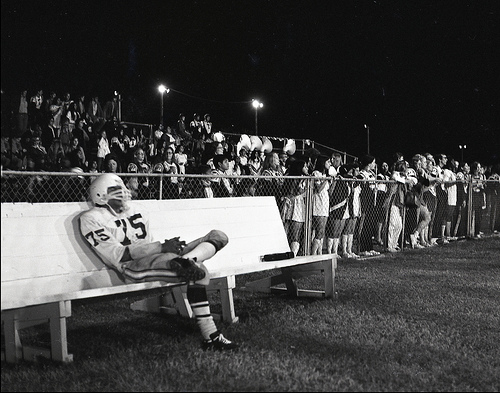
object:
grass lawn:
[0, 234, 500, 367]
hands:
[162, 236, 186, 255]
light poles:
[159, 92, 164, 124]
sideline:
[0, 55, 500, 283]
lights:
[157, 84, 171, 93]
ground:
[0, 228, 500, 366]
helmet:
[88, 172, 133, 205]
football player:
[79, 172, 241, 352]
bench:
[0, 195, 338, 364]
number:
[84, 228, 111, 247]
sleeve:
[76, 206, 126, 269]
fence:
[0, 170, 499, 257]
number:
[115, 212, 148, 246]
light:
[157, 84, 171, 94]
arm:
[78, 209, 163, 261]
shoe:
[166, 256, 206, 283]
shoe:
[200, 330, 239, 349]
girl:
[280, 157, 310, 257]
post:
[304, 179, 314, 256]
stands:
[1, 169, 498, 259]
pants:
[120, 229, 228, 283]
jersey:
[79, 206, 155, 274]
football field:
[0, 234, 499, 393]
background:
[0, 0, 500, 155]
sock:
[190, 299, 217, 340]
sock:
[181, 240, 216, 261]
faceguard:
[108, 189, 132, 211]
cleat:
[170, 257, 205, 280]